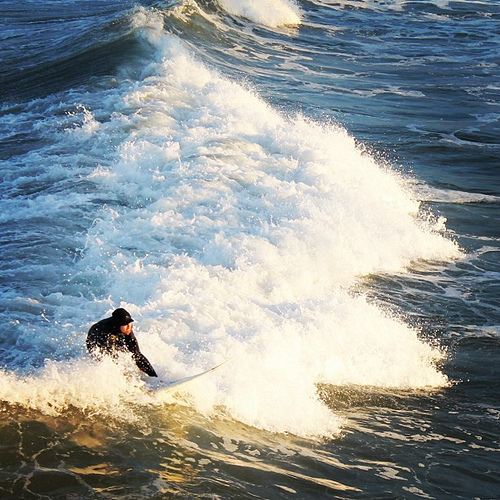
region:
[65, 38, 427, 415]
The water is rough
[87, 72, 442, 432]
The water is white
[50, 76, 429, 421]
The water is wet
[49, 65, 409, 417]
The water is splashing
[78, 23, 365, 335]
The water is vicious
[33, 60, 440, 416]
The water is rugged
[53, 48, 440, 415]
The water is tempestuous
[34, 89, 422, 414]
The water is fervent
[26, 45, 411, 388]
The water is tumultuous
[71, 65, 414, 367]
The water is boisterous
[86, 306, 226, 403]
A surfer wearing a black wetsuit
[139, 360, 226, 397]
White surfboard in the white surf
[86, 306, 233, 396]
A surfer bending down on a surfboard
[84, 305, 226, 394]
A surfer riding a wave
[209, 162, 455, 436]
A wave crashing down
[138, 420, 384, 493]
Dark and foamy ocean water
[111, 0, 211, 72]
The crest of a small wave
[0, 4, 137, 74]
The backside of a small wave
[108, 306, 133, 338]
Surfer with the hood of a wetsuit on their head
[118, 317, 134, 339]
The face of a surfer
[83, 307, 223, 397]
Surfer riding a wave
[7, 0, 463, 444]
Large wave in ocean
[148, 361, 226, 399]
Surfboard tip out of water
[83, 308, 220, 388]
Man riding a surfboard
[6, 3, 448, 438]
White spray of breaking wave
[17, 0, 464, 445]
Wave cresting on the ocean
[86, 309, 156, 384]
Black wetsuit on man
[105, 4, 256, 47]
Wave crest before breaking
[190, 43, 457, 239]
White spray of wave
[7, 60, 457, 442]
Turbulent water caused by wave breaking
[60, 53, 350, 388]
large and white waves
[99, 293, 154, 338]
man has black cap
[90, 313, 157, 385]
man has black wetsuit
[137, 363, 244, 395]
man on white board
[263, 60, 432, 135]
water is blue and white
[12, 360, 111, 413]
wave splashing near man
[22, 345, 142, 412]
white board creates wake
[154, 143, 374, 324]
water churning in waves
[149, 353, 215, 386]
man on white surfboard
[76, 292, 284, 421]
man surfing in water